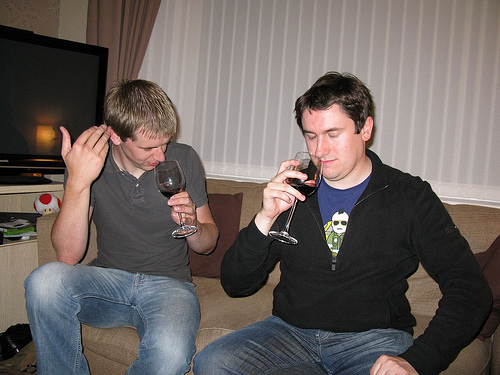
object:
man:
[217, 69, 492, 375]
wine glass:
[268, 151, 324, 245]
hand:
[260, 158, 308, 216]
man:
[23, 78, 196, 374]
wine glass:
[154, 160, 199, 241]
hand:
[166, 188, 197, 226]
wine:
[289, 175, 317, 197]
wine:
[159, 186, 181, 199]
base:
[267, 229, 299, 246]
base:
[171, 225, 199, 240]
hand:
[367, 350, 417, 374]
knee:
[338, 372, 418, 374]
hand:
[57, 122, 110, 183]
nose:
[314, 136, 331, 160]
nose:
[155, 145, 168, 163]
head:
[39, 205, 55, 214]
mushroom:
[32, 192, 62, 214]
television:
[1, 26, 110, 183]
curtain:
[102, 0, 164, 77]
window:
[133, 1, 499, 206]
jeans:
[191, 313, 412, 374]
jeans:
[22, 260, 191, 371]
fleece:
[219, 148, 493, 374]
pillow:
[185, 189, 242, 277]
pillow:
[472, 231, 499, 342]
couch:
[35, 177, 498, 374]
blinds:
[134, 1, 499, 203]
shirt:
[314, 172, 370, 273]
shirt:
[64, 137, 208, 285]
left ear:
[360, 113, 375, 144]